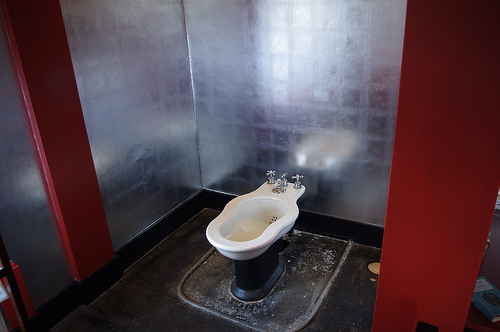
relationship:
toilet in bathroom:
[206, 169, 308, 302] [3, 1, 500, 331]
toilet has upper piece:
[206, 169, 308, 302] [205, 169, 305, 261]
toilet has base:
[206, 169, 308, 302] [229, 237, 294, 302]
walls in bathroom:
[1, 2, 499, 329] [3, 1, 500, 331]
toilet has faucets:
[206, 169, 308, 302] [286, 174, 303, 190]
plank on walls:
[3, 1, 117, 284] [1, 2, 499, 329]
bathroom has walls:
[3, 1, 500, 331] [1, 2, 499, 329]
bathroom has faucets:
[3, 1, 500, 331] [286, 174, 303, 190]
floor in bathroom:
[46, 206, 380, 331] [3, 1, 500, 331]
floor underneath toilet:
[46, 206, 380, 331] [206, 169, 308, 302]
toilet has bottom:
[206, 169, 308, 302] [177, 231, 353, 331]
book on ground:
[471, 276, 499, 322] [41, 209, 497, 327]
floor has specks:
[46, 206, 380, 331] [187, 229, 340, 318]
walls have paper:
[1, 2, 499, 329] [2, 0, 406, 311]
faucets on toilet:
[265, 168, 304, 190] [206, 169, 308, 302]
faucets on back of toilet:
[265, 168, 304, 190] [206, 169, 308, 302]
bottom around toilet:
[177, 231, 353, 331] [206, 169, 308, 302]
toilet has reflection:
[206, 169, 308, 302] [288, 126, 357, 203]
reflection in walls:
[288, 126, 357, 203] [1, 2, 499, 329]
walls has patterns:
[1, 2, 499, 329] [2, 1, 406, 310]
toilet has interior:
[206, 169, 308, 302] [217, 196, 290, 242]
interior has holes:
[217, 196, 290, 242] [267, 215, 278, 224]